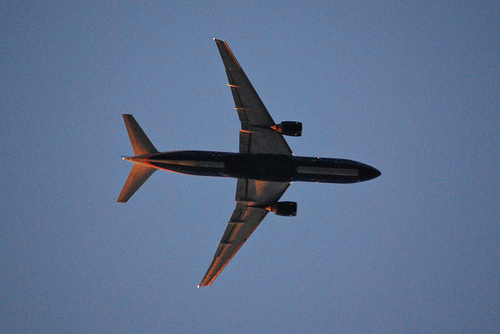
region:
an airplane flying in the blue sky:
[115, 36, 383, 287]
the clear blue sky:
[307, 3, 496, 149]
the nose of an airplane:
[359, 160, 382, 182]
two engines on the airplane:
[264, 119, 304, 216]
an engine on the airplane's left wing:
[269, 120, 302, 136]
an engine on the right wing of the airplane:
[260, 198, 297, 216]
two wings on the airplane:
[194, 38, 294, 289]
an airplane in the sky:
[5, 5, 492, 327]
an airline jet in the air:
[42, 13, 455, 305]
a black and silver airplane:
[38, 9, 460, 322]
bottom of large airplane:
[136, 150, 388, 191]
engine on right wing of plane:
[272, 200, 302, 217]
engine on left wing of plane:
[266, 121, 316, 141]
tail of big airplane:
[96, 85, 221, 229]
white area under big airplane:
[298, 150, 389, 192]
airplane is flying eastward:
[92, 44, 347, 263]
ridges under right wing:
[227, 198, 247, 243]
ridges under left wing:
[211, 47, 253, 134]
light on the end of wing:
[191, 285, 223, 295]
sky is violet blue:
[401, 61, 457, 87]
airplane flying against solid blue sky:
[13, 23, 475, 298]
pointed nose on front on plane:
[321, 156, 385, 191]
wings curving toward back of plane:
[193, 23, 296, 285]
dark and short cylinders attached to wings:
[258, 103, 305, 221]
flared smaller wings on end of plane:
[113, 103, 163, 209]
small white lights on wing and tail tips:
[116, 34, 218, 294]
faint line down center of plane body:
[128, 154, 376, 187]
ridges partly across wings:
[219, 193, 256, 265]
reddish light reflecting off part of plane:
[105, 147, 291, 288]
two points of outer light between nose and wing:
[283, 144, 381, 188]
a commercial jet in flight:
[115, 36, 380, 286]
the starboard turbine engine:
[272, 120, 302, 136]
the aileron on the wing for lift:
[227, 67, 246, 127]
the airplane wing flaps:
[236, 127, 253, 152]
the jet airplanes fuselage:
[123, 152, 382, 184]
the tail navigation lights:
[118, 153, 126, 162]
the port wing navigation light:
[192, 282, 203, 291]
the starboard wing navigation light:
[210, 34, 219, 42]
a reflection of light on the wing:
[244, 178, 269, 211]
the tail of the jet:
[116, 114, 158, 204]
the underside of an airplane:
[48, 23, 380, 286]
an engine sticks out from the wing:
[258, 120, 306, 136]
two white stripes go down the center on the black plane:
[156, 153, 368, 184]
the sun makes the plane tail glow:
[110, 108, 165, 204]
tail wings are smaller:
[117, 108, 155, 205]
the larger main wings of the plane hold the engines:
[196, 30, 304, 289]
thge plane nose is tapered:
[359, 156, 381, 183]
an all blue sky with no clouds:
[1, 2, 498, 332]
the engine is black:
[268, 201, 293, 218]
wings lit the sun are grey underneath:
[205, 36, 292, 293]